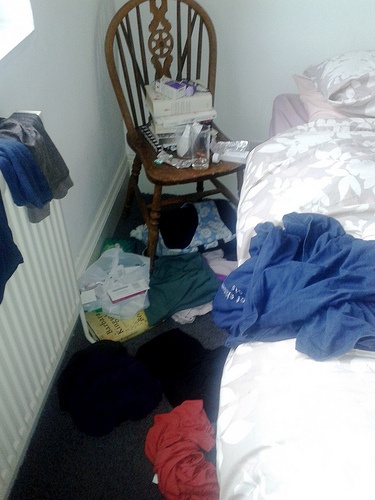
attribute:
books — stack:
[141, 76, 219, 149]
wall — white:
[3, 2, 368, 290]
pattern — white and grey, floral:
[328, 60, 361, 91]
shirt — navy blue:
[212, 207, 374, 360]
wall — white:
[1, 0, 374, 267]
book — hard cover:
[115, 282, 191, 331]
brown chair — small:
[107, 0, 217, 84]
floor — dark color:
[8, 188, 238, 498]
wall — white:
[40, 40, 102, 140]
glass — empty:
[188, 123, 212, 169]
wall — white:
[1, 0, 126, 274]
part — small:
[62, 265, 79, 294]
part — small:
[17, 212, 38, 244]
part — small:
[9, 326, 65, 404]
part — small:
[2, 413, 24, 456]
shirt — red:
[145, 396, 217, 497]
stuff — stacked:
[133, 69, 254, 172]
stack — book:
[139, 75, 220, 150]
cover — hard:
[137, 69, 225, 123]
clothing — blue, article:
[211, 212, 370, 356]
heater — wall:
[4, 112, 80, 496]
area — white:
[224, 12, 299, 82]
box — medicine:
[152, 75, 188, 102]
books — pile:
[139, 79, 220, 155]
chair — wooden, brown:
[100, 6, 256, 265]